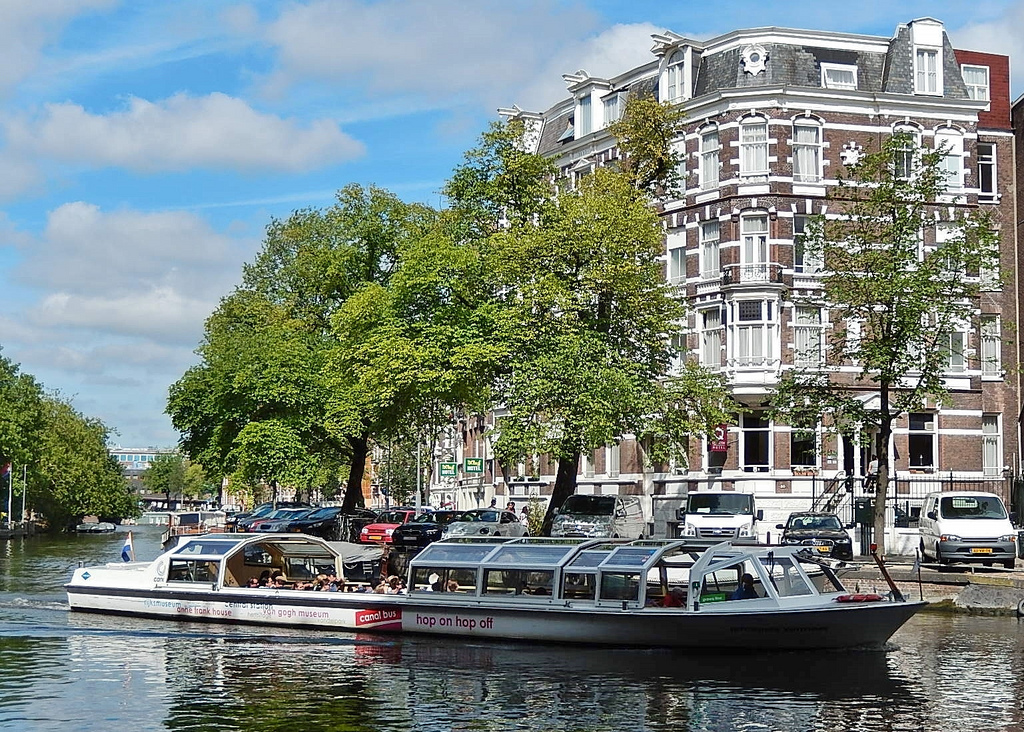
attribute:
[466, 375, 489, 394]
leaves — green 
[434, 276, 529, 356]
leaves — green 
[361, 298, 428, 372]
leaves — green 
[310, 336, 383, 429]
leaves — green 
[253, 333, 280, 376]
leaves — green 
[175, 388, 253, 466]
leaves — green 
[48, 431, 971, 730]
boat — white 